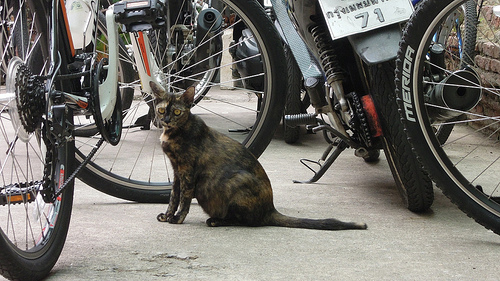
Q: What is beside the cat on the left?
A: A bicycle.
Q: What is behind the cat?
A: A bicycle.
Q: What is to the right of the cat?
A: A motorbike.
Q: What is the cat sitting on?
A: Pavement.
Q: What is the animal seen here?
A: A cat.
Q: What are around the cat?
A: Bicycles.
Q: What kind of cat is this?
A: Domestic short haired cat.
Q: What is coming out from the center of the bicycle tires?
A: Spokes.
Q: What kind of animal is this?
A: Cat.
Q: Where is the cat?
A: Sidewalk.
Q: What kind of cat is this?
A: Striped short haired cat.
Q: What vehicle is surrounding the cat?
A: Bicycle.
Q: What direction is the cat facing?
A: Left.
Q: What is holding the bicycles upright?
A: Kickstand.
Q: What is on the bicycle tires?
A: Words in white print.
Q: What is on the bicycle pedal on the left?
A: Orange reflector light.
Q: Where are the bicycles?
A: Sidewalk.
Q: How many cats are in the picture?
A: One.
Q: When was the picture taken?
A: Daytime.